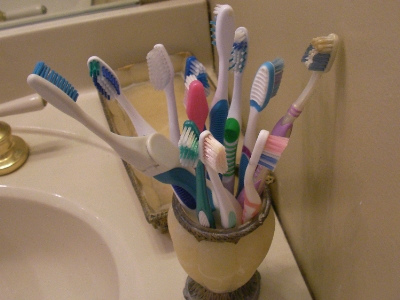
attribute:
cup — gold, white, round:
[151, 181, 303, 286]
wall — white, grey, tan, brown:
[215, 3, 399, 267]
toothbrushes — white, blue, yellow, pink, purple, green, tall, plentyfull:
[29, 6, 341, 295]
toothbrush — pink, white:
[237, 130, 293, 215]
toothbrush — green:
[219, 25, 250, 192]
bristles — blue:
[229, 26, 245, 71]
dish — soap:
[94, 48, 275, 225]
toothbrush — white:
[143, 40, 179, 138]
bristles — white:
[142, 47, 168, 92]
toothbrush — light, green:
[197, 130, 242, 227]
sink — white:
[4, 20, 315, 297]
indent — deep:
[3, 194, 122, 298]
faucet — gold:
[1, 91, 46, 176]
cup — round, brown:
[165, 185, 279, 297]